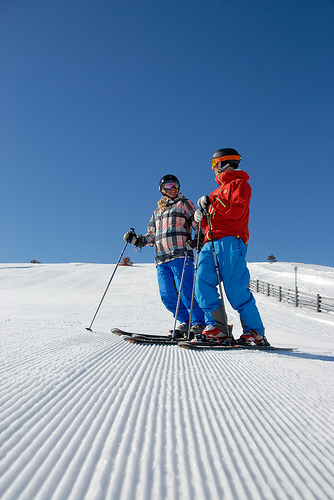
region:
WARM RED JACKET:
[196, 168, 257, 248]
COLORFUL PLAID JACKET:
[137, 196, 196, 260]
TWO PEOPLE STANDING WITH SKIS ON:
[122, 145, 297, 353]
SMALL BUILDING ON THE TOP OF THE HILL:
[28, 257, 42, 267]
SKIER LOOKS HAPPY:
[168, 187, 177, 195]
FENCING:
[250, 274, 333, 314]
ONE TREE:
[265, 252, 277, 267]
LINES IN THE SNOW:
[91, 345, 309, 498]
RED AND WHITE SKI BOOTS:
[194, 325, 266, 348]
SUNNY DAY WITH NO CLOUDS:
[5, 6, 331, 148]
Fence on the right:
[296, 289, 333, 315]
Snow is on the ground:
[111, 382, 273, 463]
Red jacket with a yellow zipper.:
[204, 172, 251, 245]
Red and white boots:
[198, 321, 270, 345]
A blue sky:
[30, 86, 159, 179]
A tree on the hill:
[266, 253, 276, 263]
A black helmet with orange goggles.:
[208, 148, 239, 175]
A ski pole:
[85, 224, 133, 335]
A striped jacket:
[151, 198, 194, 267]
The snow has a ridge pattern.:
[34, 351, 299, 440]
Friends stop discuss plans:
[148, 144, 282, 355]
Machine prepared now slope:
[6, 357, 333, 495]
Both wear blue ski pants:
[156, 234, 265, 320]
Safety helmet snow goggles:
[153, 168, 189, 206]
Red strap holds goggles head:
[203, 146, 244, 170]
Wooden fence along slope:
[251, 276, 332, 316]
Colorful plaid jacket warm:
[145, 198, 195, 264]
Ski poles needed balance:
[170, 236, 199, 343]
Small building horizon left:
[23, 257, 46, 265]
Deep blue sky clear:
[36, 167, 116, 250]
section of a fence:
[283, 291, 299, 301]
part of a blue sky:
[29, 125, 85, 187]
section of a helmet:
[219, 153, 237, 164]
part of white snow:
[95, 410, 226, 433]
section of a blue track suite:
[228, 252, 248, 294]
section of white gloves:
[194, 212, 197, 217]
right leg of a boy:
[199, 258, 207, 313]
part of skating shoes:
[247, 334, 263, 341]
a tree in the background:
[268, 258, 275, 261]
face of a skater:
[165, 185, 176, 195]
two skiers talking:
[118, 146, 294, 360]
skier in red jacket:
[193, 145, 299, 355]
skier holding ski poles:
[179, 144, 298, 356]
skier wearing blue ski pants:
[176, 146, 296, 350]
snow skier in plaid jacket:
[121, 173, 204, 344]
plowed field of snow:
[9, 349, 332, 495]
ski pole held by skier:
[82, 226, 136, 334]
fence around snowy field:
[252, 276, 333, 319]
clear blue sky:
[3, 1, 333, 257]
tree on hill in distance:
[266, 253, 276, 263]